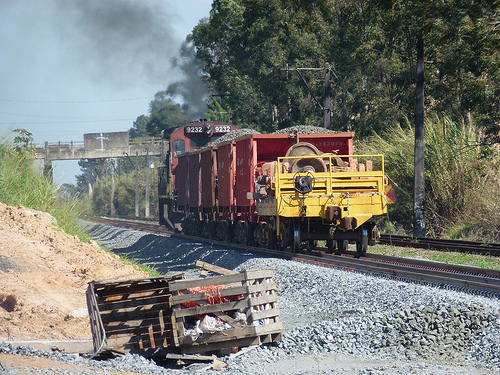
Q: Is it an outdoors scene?
A: Yes, it is outdoors.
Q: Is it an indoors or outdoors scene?
A: It is outdoors.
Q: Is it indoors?
A: No, it is outdoors.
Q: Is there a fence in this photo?
A: No, there are no fences.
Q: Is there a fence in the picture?
A: No, there are no fences.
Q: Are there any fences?
A: No, there are no fences.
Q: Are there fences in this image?
A: No, there are no fences.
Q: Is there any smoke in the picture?
A: Yes, there is smoke.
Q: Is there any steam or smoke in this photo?
A: Yes, there is smoke.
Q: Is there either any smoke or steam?
A: Yes, there is smoke.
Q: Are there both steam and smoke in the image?
A: No, there is smoke but no steam.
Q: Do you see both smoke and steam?
A: No, there is smoke but no steam.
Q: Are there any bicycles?
A: No, there are no bicycles.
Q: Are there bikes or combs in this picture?
A: No, there are no bikes or combs.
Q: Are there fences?
A: No, there are no fences.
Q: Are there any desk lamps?
A: No, there are no desk lamps.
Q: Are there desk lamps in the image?
A: No, there are no desk lamps.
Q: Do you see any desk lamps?
A: No, there are no desk lamps.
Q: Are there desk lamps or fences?
A: No, there are no desk lamps or fences.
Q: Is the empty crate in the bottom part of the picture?
A: Yes, the crate is in the bottom of the image.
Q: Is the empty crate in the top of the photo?
A: No, the crate is in the bottom of the image.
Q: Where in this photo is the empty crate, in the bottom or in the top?
A: The crate is in the bottom of the image.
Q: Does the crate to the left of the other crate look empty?
A: Yes, the crate is empty.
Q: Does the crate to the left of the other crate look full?
A: No, the crate is empty.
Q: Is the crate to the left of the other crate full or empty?
A: The crate is empty.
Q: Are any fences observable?
A: No, there are no fences.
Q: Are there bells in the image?
A: No, there are no bells.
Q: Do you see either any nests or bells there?
A: No, there are no bells or nests.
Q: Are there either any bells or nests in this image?
A: No, there are no bells or nests.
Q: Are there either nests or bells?
A: No, there are no bells or nests.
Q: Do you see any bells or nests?
A: No, there are no bells or nests.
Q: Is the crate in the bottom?
A: Yes, the crate is in the bottom of the image.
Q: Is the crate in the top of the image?
A: No, the crate is in the bottom of the image.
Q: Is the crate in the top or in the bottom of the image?
A: The crate is in the bottom of the image.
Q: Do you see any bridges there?
A: Yes, there is a bridge.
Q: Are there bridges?
A: Yes, there is a bridge.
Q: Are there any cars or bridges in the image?
A: Yes, there is a bridge.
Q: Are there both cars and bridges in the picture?
A: Yes, there are both a bridge and a car.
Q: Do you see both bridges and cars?
A: Yes, there are both a bridge and a car.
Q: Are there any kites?
A: No, there are no kites.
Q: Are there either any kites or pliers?
A: No, there are no kites or pliers.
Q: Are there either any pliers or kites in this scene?
A: No, there are no kites or pliers.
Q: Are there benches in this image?
A: No, there are no benches.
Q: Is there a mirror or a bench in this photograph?
A: No, there are no benches or mirrors.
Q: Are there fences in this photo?
A: No, there are no fences.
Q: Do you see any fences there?
A: No, there are no fences.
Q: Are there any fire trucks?
A: No, there are no fire trucks.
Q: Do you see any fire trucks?
A: No, there are no fire trucks.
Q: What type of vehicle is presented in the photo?
A: The vehicle is a car.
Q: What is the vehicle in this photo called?
A: The vehicle is a car.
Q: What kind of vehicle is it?
A: The vehicle is a car.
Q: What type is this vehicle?
A: This is a car.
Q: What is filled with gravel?
A: The car is filled with gravel.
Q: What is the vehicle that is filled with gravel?
A: The vehicle is a car.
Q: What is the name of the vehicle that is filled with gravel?
A: The vehicle is a car.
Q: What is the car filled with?
A: The car is filled with gravel.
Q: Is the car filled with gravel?
A: Yes, the car is filled with gravel.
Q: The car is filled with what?
A: The car is filled with gravel.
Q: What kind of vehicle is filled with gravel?
A: The vehicle is a car.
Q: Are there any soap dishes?
A: No, there are no soap dishes.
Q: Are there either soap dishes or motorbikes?
A: No, there are no soap dishes or motorbikes.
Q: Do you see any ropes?
A: No, there are no ropes.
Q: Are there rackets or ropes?
A: No, there are no ropes or rackets.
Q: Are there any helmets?
A: No, there are no helmets.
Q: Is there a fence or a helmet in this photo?
A: No, there are no helmets or fences.